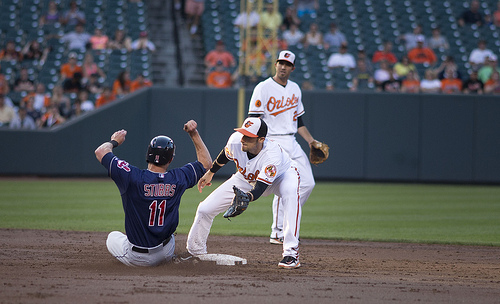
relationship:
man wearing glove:
[197, 108, 299, 270] [227, 185, 247, 218]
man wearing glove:
[246, 47, 330, 247] [310, 142, 328, 166]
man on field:
[197, 108, 299, 270] [3, 178, 496, 301]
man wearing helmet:
[93, 116, 211, 269] [145, 134, 174, 167]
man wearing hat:
[197, 108, 299, 270] [235, 119, 266, 139]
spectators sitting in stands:
[62, 25, 150, 51] [2, 2, 500, 183]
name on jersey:
[143, 185, 173, 196] [109, 158, 197, 246]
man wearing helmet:
[197, 108, 299, 270] [145, 134, 174, 167]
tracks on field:
[340, 260, 399, 296] [3, 178, 496, 301]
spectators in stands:
[62, 25, 150, 51] [2, 2, 500, 183]